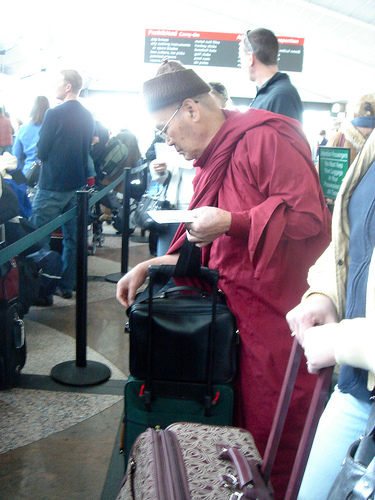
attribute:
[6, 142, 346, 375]
belt — long, green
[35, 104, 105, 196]
shirt — black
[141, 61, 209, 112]
hat — brown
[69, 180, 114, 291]
pole — tall, black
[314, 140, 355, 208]
sign — green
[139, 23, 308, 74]
red/black sign — red, black, informational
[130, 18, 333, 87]
sign — long, black, white, red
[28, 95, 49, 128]
hair — long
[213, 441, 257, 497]
handle — purple 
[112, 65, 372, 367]
man — old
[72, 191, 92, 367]
metal bar — vertical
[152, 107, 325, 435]
robe — red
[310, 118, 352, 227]
sign — green, instruction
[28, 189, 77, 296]
jean pants — blue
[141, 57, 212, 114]
cap — brown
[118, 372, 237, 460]
suitcase — green 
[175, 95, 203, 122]
ear — man's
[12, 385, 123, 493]
floor — tile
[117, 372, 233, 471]
bag — green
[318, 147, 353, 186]
sign — white, green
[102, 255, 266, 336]
travel bag — black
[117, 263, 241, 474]
suitcases — dark, stacked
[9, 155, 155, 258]
railing — rope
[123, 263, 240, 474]
suitcase — black 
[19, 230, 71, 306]
backpack — black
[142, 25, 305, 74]
sign — illegible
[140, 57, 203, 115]
hat — brown 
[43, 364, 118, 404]
stripe — dark